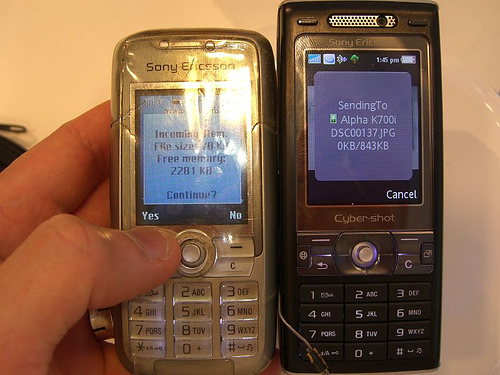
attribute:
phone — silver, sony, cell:
[113, 27, 277, 374]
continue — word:
[165, 187, 209, 202]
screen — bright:
[138, 88, 248, 225]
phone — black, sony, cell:
[276, 4, 443, 375]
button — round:
[352, 239, 378, 267]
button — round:
[176, 240, 204, 267]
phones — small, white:
[112, 3, 444, 374]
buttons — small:
[123, 239, 259, 358]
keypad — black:
[302, 281, 433, 367]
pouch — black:
[1, 119, 27, 171]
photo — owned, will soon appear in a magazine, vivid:
[3, 2, 500, 374]